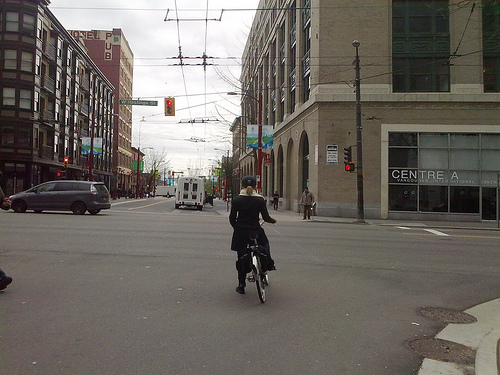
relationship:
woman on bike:
[230, 179, 278, 297] [237, 214, 270, 305]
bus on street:
[176, 177, 208, 213] [2, 200, 499, 373]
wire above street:
[0, 46, 454, 68] [2, 200, 499, 373]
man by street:
[298, 187, 316, 220] [2, 200, 499, 373]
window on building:
[21, 51, 34, 74] [0, 1, 113, 203]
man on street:
[298, 187, 316, 220] [2, 200, 499, 373]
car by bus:
[8, 178, 112, 214] [176, 177, 208, 213]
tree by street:
[141, 147, 171, 199] [2, 200, 499, 373]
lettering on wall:
[390, 167, 461, 183] [314, 0, 499, 215]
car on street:
[8, 178, 112, 214] [2, 200, 499, 373]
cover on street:
[417, 304, 475, 326] [2, 200, 499, 373]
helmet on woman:
[239, 175, 260, 189] [230, 179, 278, 297]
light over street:
[166, 99, 177, 115] [2, 200, 499, 373]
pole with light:
[352, 37, 368, 224] [166, 99, 177, 115]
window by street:
[21, 51, 34, 74] [2, 200, 499, 373]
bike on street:
[237, 214, 270, 305] [2, 200, 499, 373]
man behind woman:
[298, 187, 316, 220] [230, 179, 278, 297]